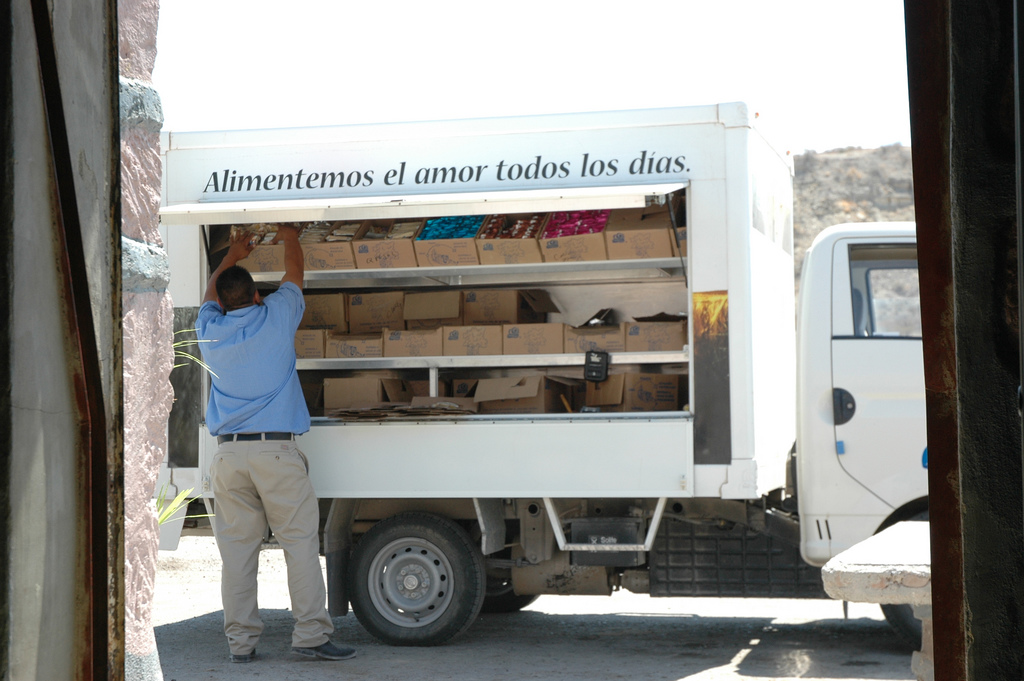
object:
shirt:
[195, 281, 312, 436]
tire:
[348, 511, 487, 647]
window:
[848, 243, 924, 339]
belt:
[217, 432, 296, 444]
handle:
[832, 387, 856, 425]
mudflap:
[325, 498, 357, 617]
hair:
[214, 264, 258, 311]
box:
[605, 203, 673, 261]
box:
[539, 208, 615, 262]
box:
[476, 212, 550, 265]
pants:
[210, 430, 334, 653]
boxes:
[210, 201, 689, 416]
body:
[194, 224, 356, 663]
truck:
[158, 100, 798, 646]